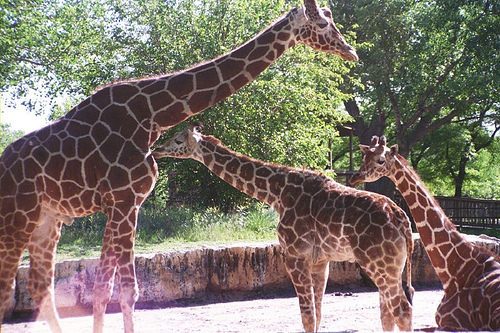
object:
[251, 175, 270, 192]
spot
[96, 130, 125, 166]
patches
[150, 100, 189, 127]
patches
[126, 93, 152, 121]
patches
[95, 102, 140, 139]
patches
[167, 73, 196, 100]
patches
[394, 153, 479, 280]
neck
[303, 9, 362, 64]
face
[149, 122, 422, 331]
giraffes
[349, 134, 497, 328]
giraffes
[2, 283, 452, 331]
field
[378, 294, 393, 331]
leg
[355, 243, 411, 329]
leg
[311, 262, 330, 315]
leg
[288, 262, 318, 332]
leg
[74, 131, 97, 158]
spot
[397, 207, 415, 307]
tail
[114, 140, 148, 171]
spot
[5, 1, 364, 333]
giraffe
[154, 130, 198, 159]
face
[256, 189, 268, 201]
spot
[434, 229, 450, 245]
brown spot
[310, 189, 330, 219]
brown spot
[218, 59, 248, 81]
brown spot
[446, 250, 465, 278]
brown spot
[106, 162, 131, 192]
brown spot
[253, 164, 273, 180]
spot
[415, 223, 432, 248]
spot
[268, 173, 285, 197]
brown spot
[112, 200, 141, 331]
leg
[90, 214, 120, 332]
leg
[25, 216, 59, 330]
leg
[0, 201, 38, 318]
leg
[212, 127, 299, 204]
neck